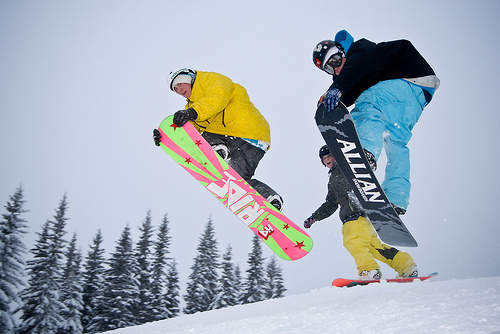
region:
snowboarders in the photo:
[103, 19, 462, 226]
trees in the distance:
[24, 226, 187, 321]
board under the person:
[153, 111, 324, 264]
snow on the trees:
[5, 227, 162, 327]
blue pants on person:
[349, 70, 436, 178]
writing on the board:
[328, 133, 399, 243]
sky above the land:
[51, 26, 143, 122]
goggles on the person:
[308, 34, 355, 86]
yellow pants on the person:
[319, 193, 405, 288]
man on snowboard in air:
[144, 59, 296, 241]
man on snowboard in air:
[308, 28, 449, 210]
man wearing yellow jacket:
[197, 77, 254, 144]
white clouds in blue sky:
[100, 135, 125, 180]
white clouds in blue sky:
[426, 7, 479, 58]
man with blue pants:
[361, 81, 412, 186]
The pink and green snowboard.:
[161, 111, 316, 266]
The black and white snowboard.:
[315, 103, 414, 260]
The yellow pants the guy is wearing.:
[343, 218, 415, 278]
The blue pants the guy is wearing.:
[359, 87, 414, 202]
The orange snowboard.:
[325, 275, 441, 285]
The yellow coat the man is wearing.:
[173, 66, 275, 146]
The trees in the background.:
[4, 176, 289, 332]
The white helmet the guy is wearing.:
[166, 68, 190, 84]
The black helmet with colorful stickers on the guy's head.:
[306, 41, 331, 68]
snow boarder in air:
[144, 47, 285, 247]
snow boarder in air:
[294, 30, 456, 222]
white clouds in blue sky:
[25, 33, 63, 68]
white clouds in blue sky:
[0, 92, 50, 142]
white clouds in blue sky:
[86, 45, 110, 77]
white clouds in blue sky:
[247, 19, 285, 60]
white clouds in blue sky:
[174, 22, 223, 60]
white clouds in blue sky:
[56, 8, 111, 66]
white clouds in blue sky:
[71, 152, 118, 207]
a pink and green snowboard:
[133, 107, 342, 280]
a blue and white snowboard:
[303, 79, 435, 294]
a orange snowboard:
[317, 271, 448, 312]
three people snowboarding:
[135, 53, 457, 282]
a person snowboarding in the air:
[135, 60, 306, 294]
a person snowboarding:
[298, 133, 436, 298]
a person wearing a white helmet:
[141, 60, 211, 105]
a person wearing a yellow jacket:
[136, 60, 268, 162]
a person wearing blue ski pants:
[302, 33, 458, 230]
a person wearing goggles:
[307, 35, 368, 98]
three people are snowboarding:
[151, 29, 445, 286]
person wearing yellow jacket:
[151, 62, 315, 262]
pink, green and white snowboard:
[153, 114, 314, 264]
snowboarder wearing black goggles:
[312, 32, 438, 248]